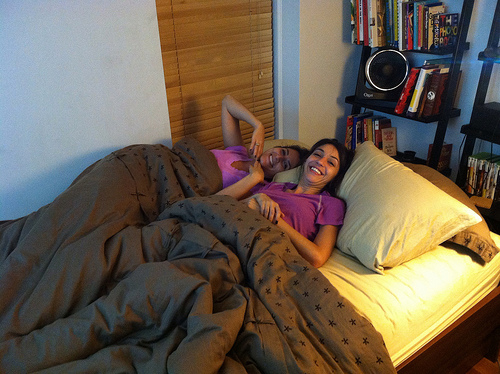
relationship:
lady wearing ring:
[208, 95, 311, 201] [246, 138, 260, 148]